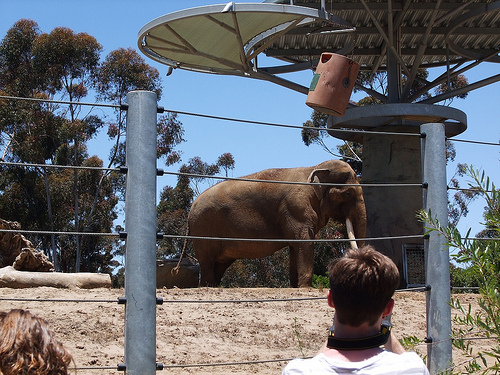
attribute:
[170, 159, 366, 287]
elephant — large, mature, brown-gray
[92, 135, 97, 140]
leaf — green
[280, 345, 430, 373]
t-shirt — white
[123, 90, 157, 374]
pole — metallic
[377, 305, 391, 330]
recording device — electronic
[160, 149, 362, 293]
elephant — brownish grey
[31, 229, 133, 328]
trunk — tree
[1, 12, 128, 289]
trees — tall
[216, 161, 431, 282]
elephant — dusty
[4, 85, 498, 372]
fence — wire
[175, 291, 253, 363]
dirt — tan